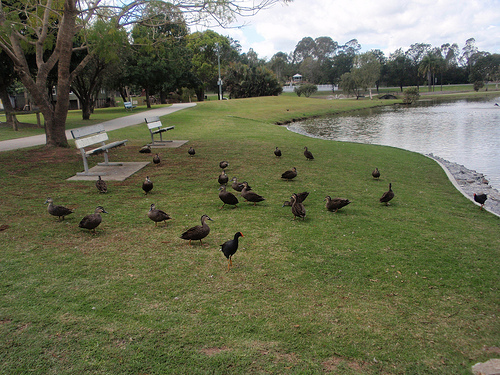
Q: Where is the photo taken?
A: A park.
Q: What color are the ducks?
A: Black.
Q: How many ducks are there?
A: Twenty-three.